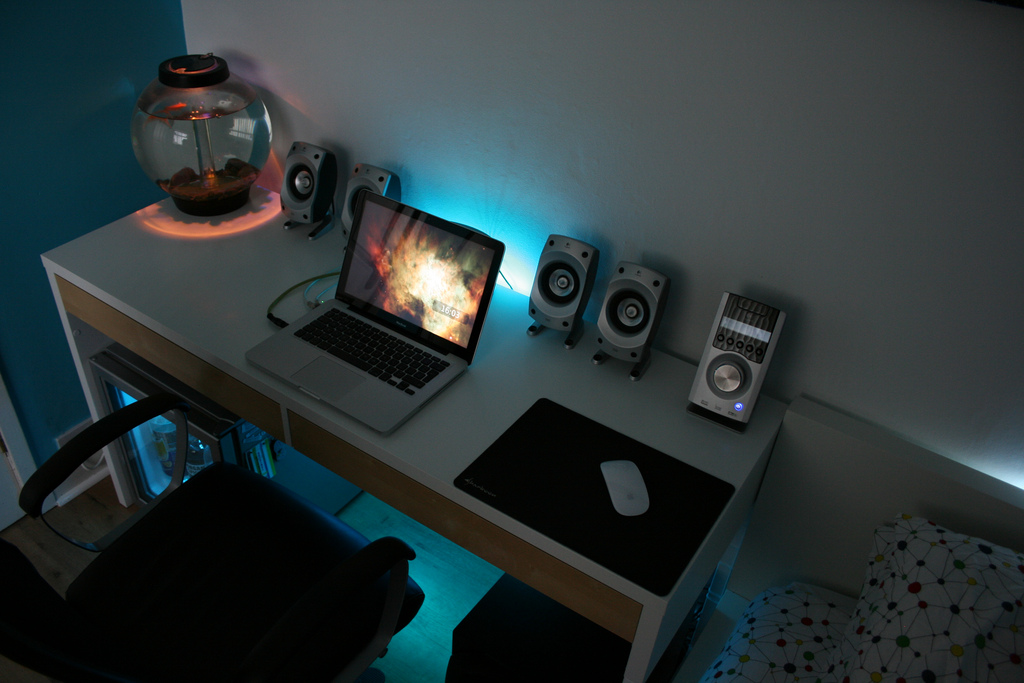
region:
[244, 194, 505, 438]
an opened silver and black laptop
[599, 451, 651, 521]
a white mouse on a black mouse pad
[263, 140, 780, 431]
a row of silver speakers on a desk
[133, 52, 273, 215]
an aquarium sitting on a desk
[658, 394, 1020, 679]
the white frame of a bed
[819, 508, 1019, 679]
a pillow on top of a mattress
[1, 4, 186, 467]
a blue wall in a bedroom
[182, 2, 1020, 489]
a white wall in a bedroom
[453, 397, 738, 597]
a black rectangular mouse pad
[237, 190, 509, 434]
Laptop with a fiery screen saver.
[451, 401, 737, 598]
Black mouse pad with a white mouse on top.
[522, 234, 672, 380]
Two speaker sitting next to one another.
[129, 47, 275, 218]
Sphere shaped fish tank filled with water.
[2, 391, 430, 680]
Black office chair pulled in front of a desk.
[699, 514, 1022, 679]
Atom designed furniture and pillow case.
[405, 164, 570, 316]
A blue glow illuminating the wall.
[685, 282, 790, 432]
A music player with a circle dial.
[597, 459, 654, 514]
White wireless mouse for computer.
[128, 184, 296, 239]
Orange glow on white desk from tank.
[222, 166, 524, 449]
Laptop is on a desk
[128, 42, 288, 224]
Fish bowl on a desk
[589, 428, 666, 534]
Mouse on a mousepad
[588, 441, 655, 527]
Mouse is on a mouse pad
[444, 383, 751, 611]
Mouse pad is on a desk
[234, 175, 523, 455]
Laptop on a white desk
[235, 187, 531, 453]
Laptop is on a white desk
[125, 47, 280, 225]
A FISH BOWL ON THE DESK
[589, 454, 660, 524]
A WHITE COMPUTER MOUSE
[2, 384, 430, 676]
A BLACK OFFICE CHAIR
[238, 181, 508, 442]
AN OPEN LAPTOP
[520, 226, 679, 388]
TWO SPEAKERS ON A DESK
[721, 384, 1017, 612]
A WHITE HEADBOARD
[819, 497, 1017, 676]
A PILLOW ON A BED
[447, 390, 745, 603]
A BLACK MOUSE PAD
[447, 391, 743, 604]
A MOUSE ON A MOUSE PAD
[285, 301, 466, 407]
BLACK KEYS ON A LAPTOP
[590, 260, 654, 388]
speaker on the desk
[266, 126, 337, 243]
speaker on the desk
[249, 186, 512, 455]
Laptop on the desk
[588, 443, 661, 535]
mouse on the desk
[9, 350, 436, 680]
chair near the desk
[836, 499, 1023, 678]
pillow on the bed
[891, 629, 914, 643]
A black dot on a pillowcase.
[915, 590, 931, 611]
A black dot on a pillowcase.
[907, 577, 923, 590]
A black dot on a pillowcase.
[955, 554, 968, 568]
A black dot on a pillowcase.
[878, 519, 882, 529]
A black dot on a pillowcase.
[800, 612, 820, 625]
A black dot on a pillowcase.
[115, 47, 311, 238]
fishbowl on white table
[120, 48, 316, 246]
fishbowl on white table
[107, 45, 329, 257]
fishbowl on white table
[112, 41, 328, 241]
fishbowl on white table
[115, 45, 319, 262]
fishbowl on white table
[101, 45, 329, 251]
fishbowl on white table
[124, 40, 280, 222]
a fish tank on a table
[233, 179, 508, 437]
laptop on top of a desk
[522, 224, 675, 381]
speakers on a desk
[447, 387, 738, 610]
mouse on top of a mouse pad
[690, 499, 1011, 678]
pillows on the floor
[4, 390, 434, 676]
chair next to a desk